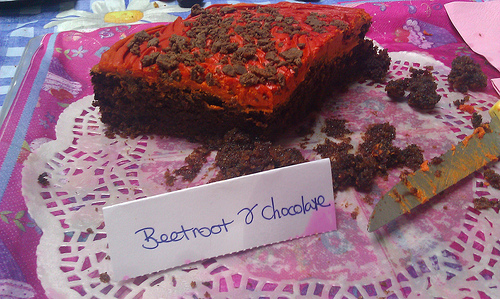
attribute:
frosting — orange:
[99, 2, 373, 107]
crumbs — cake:
[165, 44, 484, 194]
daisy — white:
[61, 6, 171, 51]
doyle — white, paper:
[21, 35, 499, 295]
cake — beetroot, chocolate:
[98, 0, 389, 134]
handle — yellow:
[488, 97, 498, 122]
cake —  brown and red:
[89, 0, 371, 139]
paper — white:
[83, 152, 348, 287]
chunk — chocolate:
[279, 45, 302, 60]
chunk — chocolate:
[141, 50, 159, 67]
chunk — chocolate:
[157, 52, 178, 72]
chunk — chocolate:
[145, 36, 157, 47]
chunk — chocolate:
[257, 36, 271, 45]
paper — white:
[102, 157, 337, 282]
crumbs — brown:
[199, 122, 422, 188]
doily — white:
[21, 35, 498, 297]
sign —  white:
[99, 155, 345, 277]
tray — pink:
[6, 15, 498, 297]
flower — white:
[52, 0, 182, 25]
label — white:
[100, 157, 367, 283]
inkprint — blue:
[137, 210, 244, 247]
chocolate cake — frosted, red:
[66, 8, 496, 288]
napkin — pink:
[443, 1, 498, 71]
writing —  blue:
[134, 192, 333, 250]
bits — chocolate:
[155, 33, 294, 69]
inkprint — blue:
[256, 197, 342, 223]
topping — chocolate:
[122, 36, 228, 81]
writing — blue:
[145, 188, 330, 252]